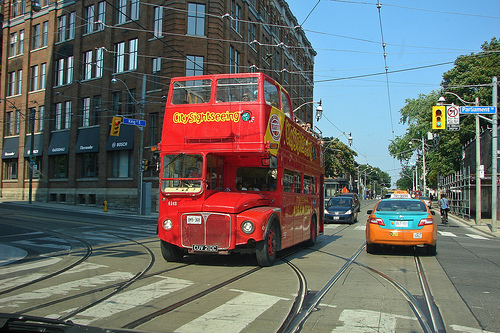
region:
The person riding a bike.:
[437, 191, 457, 227]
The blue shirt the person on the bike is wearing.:
[436, 198, 453, 211]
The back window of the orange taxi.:
[380, 199, 425, 212]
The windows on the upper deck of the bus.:
[167, 80, 295, 115]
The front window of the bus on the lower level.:
[163, 152, 203, 196]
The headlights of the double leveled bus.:
[152, 210, 258, 240]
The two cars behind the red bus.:
[322, 180, 361, 230]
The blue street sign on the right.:
[456, 105, 493, 116]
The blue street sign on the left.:
[122, 115, 147, 127]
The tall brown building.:
[3, 0, 320, 225]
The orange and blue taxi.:
[367, 197, 437, 242]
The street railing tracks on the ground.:
[11, 211, 446, 328]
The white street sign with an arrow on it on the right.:
[446, 106, 466, 124]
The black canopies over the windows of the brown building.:
[1, 130, 135, 150]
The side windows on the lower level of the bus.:
[280, 166, 321, 197]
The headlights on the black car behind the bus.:
[324, 205, 354, 220]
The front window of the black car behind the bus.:
[330, 195, 352, 207]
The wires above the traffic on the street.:
[16, 8, 498, 104]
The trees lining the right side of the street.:
[386, 44, 498, 186]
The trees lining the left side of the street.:
[322, 120, 392, 200]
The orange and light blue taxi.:
[365, 188, 435, 247]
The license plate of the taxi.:
[395, 219, 409, 229]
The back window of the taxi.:
[380, 200, 422, 212]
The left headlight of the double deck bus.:
[164, 215, 171, 232]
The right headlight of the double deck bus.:
[240, 219, 255, 234]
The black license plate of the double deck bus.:
[186, 243, 225, 256]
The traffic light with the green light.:
[430, 103, 442, 130]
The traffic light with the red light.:
[106, 113, 125, 138]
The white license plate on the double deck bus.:
[181, 214, 205, 224]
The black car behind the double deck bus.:
[320, 180, 355, 226]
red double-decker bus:
[160, 74, 325, 261]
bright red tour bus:
[160, 75, 325, 262]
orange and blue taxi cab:
[367, 190, 434, 254]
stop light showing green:
[432, 106, 443, 129]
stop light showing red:
[108, 116, 120, 136]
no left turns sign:
[446, 103, 458, 124]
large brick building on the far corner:
[0, 0, 314, 207]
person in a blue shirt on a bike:
[438, 193, 448, 223]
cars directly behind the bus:
[328, 187, 358, 222]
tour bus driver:
[187, 160, 212, 185]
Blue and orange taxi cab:
[367, 191, 438, 252]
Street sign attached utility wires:
[120, 115, 147, 127]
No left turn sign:
[445, 104, 457, 128]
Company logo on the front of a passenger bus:
[170, 108, 242, 123]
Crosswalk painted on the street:
[2, 253, 499, 331]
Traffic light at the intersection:
[430, 105, 446, 130]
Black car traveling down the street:
[322, 196, 357, 222]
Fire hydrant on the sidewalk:
[102, 200, 105, 210]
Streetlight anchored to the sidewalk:
[436, 90, 481, 227]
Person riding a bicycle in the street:
[439, 192, 449, 222]